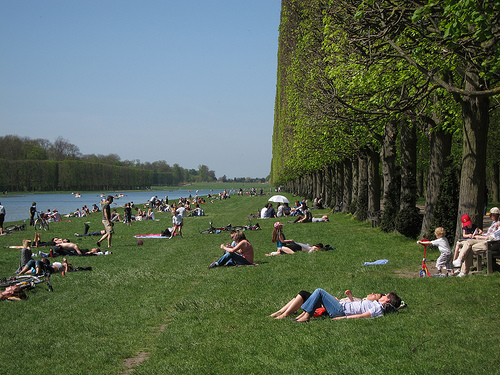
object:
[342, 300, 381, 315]
shirt